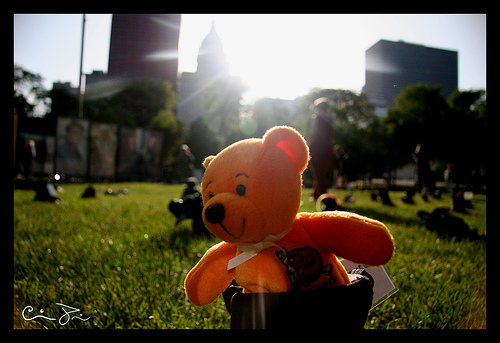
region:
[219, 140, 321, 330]
A toy bear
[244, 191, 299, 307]
A toy bear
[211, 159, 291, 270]
A toy bear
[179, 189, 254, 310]
A toy bear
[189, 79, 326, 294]
A toy bear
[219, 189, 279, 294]
A toy bear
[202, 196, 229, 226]
the nose of the teddy bear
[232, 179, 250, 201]
the eye of the teddy bear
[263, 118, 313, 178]
the ear of the teddy bear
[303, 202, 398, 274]
the arm of the teddy bear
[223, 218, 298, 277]
a white bow on the teddy bear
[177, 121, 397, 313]
a yellow teddy bear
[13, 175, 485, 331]
a green grassy field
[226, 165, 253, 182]
the eyebrow of the teddy bear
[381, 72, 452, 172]
a leafy green tree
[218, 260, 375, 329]
a small black bucket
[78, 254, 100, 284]
the grass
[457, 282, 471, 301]
the grass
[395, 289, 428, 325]
the grass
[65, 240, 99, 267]
the grass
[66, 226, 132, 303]
the grass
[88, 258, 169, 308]
the grass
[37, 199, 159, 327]
the grass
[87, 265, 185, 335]
the grass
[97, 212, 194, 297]
the grass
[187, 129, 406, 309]
orange stuffed teddy bear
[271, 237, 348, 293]
embroidered beaver on a bear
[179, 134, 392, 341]
small orange teddy bear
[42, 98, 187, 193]
large blurry bill boards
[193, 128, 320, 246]
orange teddy bear's face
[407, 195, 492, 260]
shadow of person walking in field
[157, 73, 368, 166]
bright sunlight and rays of sun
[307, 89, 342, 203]
person walking in a field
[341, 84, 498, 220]
row of trees in the grass field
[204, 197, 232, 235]
black stuffed bear nose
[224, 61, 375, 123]
the sky is clear and visible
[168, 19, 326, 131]
the sky is clear and visible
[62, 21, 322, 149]
the sky is clear and visible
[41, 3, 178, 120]
the sky is clear and visible